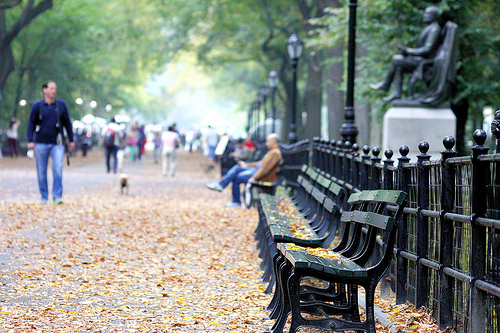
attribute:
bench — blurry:
[223, 138, 347, 249]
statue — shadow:
[378, 24, 476, 114]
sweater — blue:
[28, 104, 72, 143]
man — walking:
[23, 80, 75, 202]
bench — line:
[264, 188, 406, 330]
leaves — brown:
[1, 0, 499, 331]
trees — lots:
[0, 0, 185, 132]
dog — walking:
[112, 162, 144, 202]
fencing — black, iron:
[298, 142, 492, 313]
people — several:
[159, 121, 180, 172]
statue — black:
[370, 10, 465, 110]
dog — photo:
[104, 159, 151, 201]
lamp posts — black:
[242, 29, 307, 146]